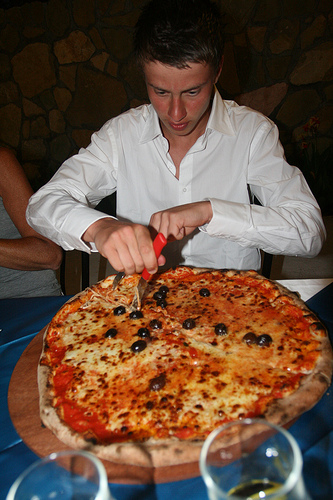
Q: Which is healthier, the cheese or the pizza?
A: The cheese is healthier than the pizza.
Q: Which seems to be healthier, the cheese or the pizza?
A: The cheese is healthier than the pizza.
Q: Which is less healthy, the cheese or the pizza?
A: The pizza is less healthy than the cheese.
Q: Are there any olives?
A: Yes, there are olives.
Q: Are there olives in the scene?
A: Yes, there are olives.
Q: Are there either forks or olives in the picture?
A: Yes, there are olives.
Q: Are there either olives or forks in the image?
A: Yes, there are olives.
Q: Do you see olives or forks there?
A: Yes, there are olives.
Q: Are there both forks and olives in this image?
A: Yes, there are both olives and a fork.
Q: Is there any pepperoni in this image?
A: No, there is no pepperoni.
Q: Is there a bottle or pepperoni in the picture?
A: No, there are no pepperoni or bottles.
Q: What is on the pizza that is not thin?
A: The olives are on the pizza.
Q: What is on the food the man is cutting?
A: The olives are on the pizza.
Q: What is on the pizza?
A: The olives are on the pizza.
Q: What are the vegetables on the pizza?
A: The vegetables are olives.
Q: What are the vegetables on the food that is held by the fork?
A: The vegetables are olives.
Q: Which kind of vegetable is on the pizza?
A: The vegetables are olives.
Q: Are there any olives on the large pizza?
A: Yes, there are olives on the pizza.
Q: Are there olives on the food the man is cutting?
A: Yes, there are olives on the pizza.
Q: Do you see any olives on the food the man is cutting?
A: Yes, there are olives on the pizza.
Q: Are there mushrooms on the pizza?
A: No, there are olives on the pizza.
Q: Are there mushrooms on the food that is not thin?
A: No, there are olives on the pizza.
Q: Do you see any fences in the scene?
A: No, there are no fences.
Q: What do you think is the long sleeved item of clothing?
A: The clothing item is a shirt.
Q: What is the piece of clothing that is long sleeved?
A: The clothing item is a shirt.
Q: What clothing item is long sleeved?
A: The clothing item is a shirt.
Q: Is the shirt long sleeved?
A: Yes, the shirt is long sleeved.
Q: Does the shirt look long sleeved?
A: Yes, the shirt is long sleeved.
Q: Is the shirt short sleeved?
A: No, the shirt is long sleeved.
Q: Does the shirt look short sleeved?
A: No, the shirt is long sleeved.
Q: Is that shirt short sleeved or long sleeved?
A: The shirt is long sleeved.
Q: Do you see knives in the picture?
A: Yes, there is a knife.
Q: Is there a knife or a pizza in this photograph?
A: Yes, there is a knife.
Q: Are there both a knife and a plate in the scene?
A: No, there is a knife but no plates.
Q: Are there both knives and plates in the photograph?
A: No, there is a knife but no plates.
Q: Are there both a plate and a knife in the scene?
A: No, there is a knife but no plates.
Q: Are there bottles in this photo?
A: No, there are no bottles.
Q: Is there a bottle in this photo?
A: No, there are no bottles.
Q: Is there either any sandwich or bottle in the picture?
A: No, there are no bottles or sandwiches.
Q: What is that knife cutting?
A: The knife is cutting the pizza.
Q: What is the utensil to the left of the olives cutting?
A: The knife is cutting the pizza.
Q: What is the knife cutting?
A: The knife is cutting the pizza.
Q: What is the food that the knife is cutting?
A: The food is a pizza.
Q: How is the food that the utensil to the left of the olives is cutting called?
A: The food is a pizza.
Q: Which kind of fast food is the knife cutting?
A: The knife is cutting the pizza.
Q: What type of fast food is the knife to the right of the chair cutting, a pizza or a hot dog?
A: The knife is cutting a pizza.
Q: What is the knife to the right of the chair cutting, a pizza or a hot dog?
A: The knife is cutting a pizza.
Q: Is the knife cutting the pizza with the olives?
A: Yes, the knife is cutting the pizza.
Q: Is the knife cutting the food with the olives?
A: Yes, the knife is cutting the pizza.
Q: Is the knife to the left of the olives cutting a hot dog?
A: No, the knife is cutting the pizza.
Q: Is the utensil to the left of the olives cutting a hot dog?
A: No, the knife is cutting the pizza.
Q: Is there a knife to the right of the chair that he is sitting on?
A: Yes, there is a knife to the right of the chair.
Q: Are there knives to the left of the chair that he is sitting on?
A: No, the knife is to the right of the chair.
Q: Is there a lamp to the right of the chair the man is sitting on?
A: No, there is a knife to the right of the chair.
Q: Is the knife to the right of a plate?
A: No, the knife is to the right of the chair.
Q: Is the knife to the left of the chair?
A: No, the knife is to the right of the chair.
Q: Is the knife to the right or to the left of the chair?
A: The knife is to the right of the chair.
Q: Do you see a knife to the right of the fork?
A: Yes, there is a knife to the right of the fork.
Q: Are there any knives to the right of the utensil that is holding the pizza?
A: Yes, there is a knife to the right of the fork.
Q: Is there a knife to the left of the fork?
A: No, the knife is to the right of the fork.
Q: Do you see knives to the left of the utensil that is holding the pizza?
A: No, the knife is to the right of the fork.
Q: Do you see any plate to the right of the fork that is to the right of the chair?
A: No, there is a knife to the right of the fork.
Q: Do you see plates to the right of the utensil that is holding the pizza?
A: No, there is a knife to the right of the fork.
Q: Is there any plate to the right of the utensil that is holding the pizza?
A: No, there is a knife to the right of the fork.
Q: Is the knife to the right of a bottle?
A: No, the knife is to the right of the fork.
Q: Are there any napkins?
A: No, there are no napkins.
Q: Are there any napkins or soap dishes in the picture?
A: No, there are no napkins or soap dishes.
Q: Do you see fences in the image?
A: No, there are no fences.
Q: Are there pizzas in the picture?
A: Yes, there is a pizza.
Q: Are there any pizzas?
A: Yes, there is a pizza.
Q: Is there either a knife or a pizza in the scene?
A: Yes, there is a pizza.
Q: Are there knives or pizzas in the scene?
A: Yes, there is a pizza.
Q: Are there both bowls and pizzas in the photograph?
A: No, there is a pizza but no bowls.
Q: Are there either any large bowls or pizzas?
A: Yes, there is a large pizza.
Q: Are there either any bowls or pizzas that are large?
A: Yes, the pizza is large.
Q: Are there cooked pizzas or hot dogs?
A: Yes, there is a cooked pizza.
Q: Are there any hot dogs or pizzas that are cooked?
A: Yes, the pizza is cooked.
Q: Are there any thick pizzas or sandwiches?
A: Yes, there is a thick pizza.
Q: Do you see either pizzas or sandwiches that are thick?
A: Yes, the pizza is thick.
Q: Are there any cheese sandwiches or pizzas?
A: Yes, there is a cheese pizza.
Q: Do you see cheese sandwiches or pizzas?
A: Yes, there is a cheese pizza.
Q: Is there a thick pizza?
A: Yes, there is a thick pizza.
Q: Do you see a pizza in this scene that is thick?
A: Yes, there is a pizza that is thick.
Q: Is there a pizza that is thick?
A: Yes, there is a pizza that is thick.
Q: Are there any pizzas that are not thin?
A: Yes, there is a thick pizza.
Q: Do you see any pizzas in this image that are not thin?
A: Yes, there is a thick pizza.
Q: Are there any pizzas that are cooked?
A: Yes, there is a cooked pizza.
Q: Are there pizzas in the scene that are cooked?
A: Yes, there is a pizza that is cooked.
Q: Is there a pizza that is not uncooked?
A: Yes, there is an cooked pizza.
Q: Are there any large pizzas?
A: Yes, there is a large pizza.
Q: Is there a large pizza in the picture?
A: Yes, there is a large pizza.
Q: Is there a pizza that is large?
A: Yes, there is a pizza that is large.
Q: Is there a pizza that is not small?
A: Yes, there is a large pizza.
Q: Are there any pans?
A: No, there are no pans.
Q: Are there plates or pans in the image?
A: No, there are no pans or plates.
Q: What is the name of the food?
A: The food is a pizza.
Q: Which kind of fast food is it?
A: The food is a pizza.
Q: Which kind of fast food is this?
A: This is a pizza.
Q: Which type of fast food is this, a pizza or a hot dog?
A: This is a pizza.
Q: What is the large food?
A: The food is a pizza.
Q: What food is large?
A: The food is a pizza.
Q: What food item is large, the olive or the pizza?
A: The pizza is large.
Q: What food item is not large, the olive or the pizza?
A: The olive is not large.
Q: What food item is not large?
A: The food item is an olive.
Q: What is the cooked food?
A: The food is a pizza.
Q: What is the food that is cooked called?
A: The food is a pizza.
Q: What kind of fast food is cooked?
A: The fast food is a pizza.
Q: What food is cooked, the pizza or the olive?
A: The pizza is cooked.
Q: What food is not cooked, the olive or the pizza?
A: The olive is not cooked.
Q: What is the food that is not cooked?
A: The food is an olive.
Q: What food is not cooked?
A: The food is an olive.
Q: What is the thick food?
A: The food is a pizza.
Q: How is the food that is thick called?
A: The food is a pizza.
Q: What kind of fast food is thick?
A: The fast food is a pizza.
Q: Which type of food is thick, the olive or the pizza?
A: The pizza is thick.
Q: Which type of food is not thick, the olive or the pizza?
A: The olive is not thick.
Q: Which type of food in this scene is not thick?
A: The food is an olive.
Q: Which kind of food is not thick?
A: The food is an olive.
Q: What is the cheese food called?
A: The food is a pizza.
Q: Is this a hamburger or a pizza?
A: This is a pizza.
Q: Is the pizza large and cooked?
A: Yes, the pizza is large and cooked.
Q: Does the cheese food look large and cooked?
A: Yes, the pizza is large and cooked.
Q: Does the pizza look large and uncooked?
A: No, the pizza is large but cooked.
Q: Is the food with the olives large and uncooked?
A: No, the pizza is large but cooked.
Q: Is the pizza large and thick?
A: Yes, the pizza is large and thick.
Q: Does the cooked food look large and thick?
A: Yes, the pizza is large and thick.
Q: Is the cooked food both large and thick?
A: Yes, the pizza is large and thick.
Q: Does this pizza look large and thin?
A: No, the pizza is large but thick.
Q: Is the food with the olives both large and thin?
A: No, the pizza is large but thick.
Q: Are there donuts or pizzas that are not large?
A: No, there is a pizza but it is large.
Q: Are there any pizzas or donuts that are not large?
A: No, there is a pizza but it is large.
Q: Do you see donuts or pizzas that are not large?
A: No, there is a pizza but it is large.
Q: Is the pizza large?
A: Yes, the pizza is large.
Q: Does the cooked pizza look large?
A: Yes, the pizza is large.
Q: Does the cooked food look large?
A: Yes, the pizza is large.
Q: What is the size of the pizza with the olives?
A: The pizza is large.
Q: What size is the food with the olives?
A: The pizza is large.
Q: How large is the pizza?
A: The pizza is large.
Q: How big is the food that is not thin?
A: The pizza is large.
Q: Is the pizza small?
A: No, the pizza is large.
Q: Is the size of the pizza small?
A: No, the pizza is large.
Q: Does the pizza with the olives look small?
A: No, the pizza is large.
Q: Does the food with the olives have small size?
A: No, the pizza is large.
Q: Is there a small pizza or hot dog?
A: No, there is a pizza but it is large.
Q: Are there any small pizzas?
A: No, there is a pizza but it is large.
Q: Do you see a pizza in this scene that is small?
A: No, there is a pizza but it is large.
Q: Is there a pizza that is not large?
A: No, there is a pizza but it is large.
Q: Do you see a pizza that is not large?
A: No, there is a pizza but it is large.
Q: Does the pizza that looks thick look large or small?
A: The pizza is large.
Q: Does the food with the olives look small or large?
A: The pizza is large.